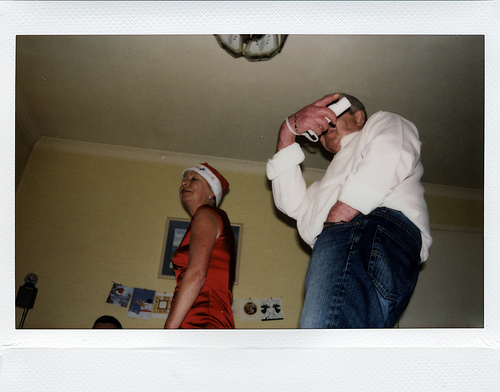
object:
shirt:
[266, 110, 433, 259]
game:
[315, 86, 353, 128]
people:
[139, 153, 292, 339]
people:
[301, 96, 431, 346]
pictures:
[100, 269, 274, 326]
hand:
[325, 199, 375, 224]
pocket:
[323, 214, 369, 268]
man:
[280, 94, 464, 369]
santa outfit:
[163, 152, 237, 329]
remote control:
[288, 91, 343, 136]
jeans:
[299, 206, 422, 327]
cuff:
[258, 130, 312, 192]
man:
[255, 66, 449, 334]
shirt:
[260, 104, 459, 252]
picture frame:
[160, 217, 243, 283]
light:
[211, 30, 292, 62]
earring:
[201, 188, 223, 207]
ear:
[353, 96, 370, 129]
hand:
[320, 200, 360, 226]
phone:
[306, 80, 374, 131]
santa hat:
[178, 159, 235, 210]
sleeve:
[270, 151, 324, 230]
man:
[276, 60, 428, 342]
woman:
[175, 163, 233, 329]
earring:
[207, 190, 215, 200]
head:
[168, 147, 256, 210]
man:
[265, 90, 434, 325]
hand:
[285, 90, 346, 136]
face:
[319, 110, 358, 145]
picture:
[157, 207, 248, 287]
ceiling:
[40, 32, 233, 136]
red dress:
[177, 210, 243, 331]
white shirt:
[251, 109, 436, 258]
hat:
[185, 160, 227, 200]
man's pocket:
[311, 213, 360, 252]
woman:
[158, 162, 240, 331]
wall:
[90, 220, 157, 318]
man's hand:
[287, 91, 341, 137]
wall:
[23, 132, 483, 324]